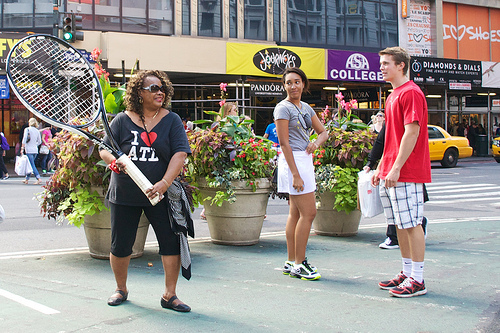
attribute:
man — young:
[369, 44, 430, 301]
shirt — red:
[382, 80, 434, 185]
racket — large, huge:
[7, 32, 164, 207]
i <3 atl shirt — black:
[99, 108, 191, 205]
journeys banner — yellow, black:
[225, 40, 333, 79]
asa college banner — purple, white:
[327, 49, 401, 81]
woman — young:
[271, 66, 332, 281]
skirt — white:
[273, 148, 319, 198]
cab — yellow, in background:
[423, 120, 473, 171]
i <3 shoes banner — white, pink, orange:
[441, 2, 499, 63]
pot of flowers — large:
[182, 113, 280, 246]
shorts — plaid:
[378, 177, 428, 229]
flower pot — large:
[42, 113, 156, 256]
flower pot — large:
[299, 115, 379, 233]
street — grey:
[1, 158, 498, 253]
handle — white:
[118, 152, 164, 206]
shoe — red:
[379, 271, 408, 292]